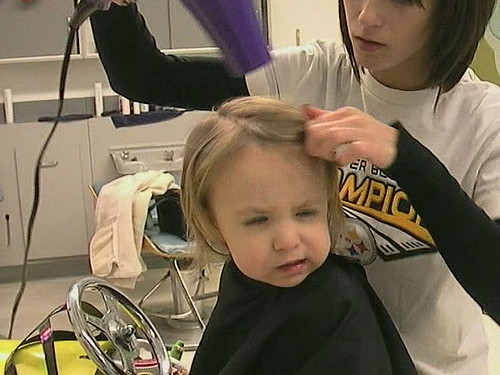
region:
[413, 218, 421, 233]
part of a shirt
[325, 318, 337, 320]
part of a shoulder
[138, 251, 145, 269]
part of a table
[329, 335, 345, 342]
part of a cloth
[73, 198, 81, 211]
part of a drawer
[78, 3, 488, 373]
A child getting their hair styled.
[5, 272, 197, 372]
Racecar chair at a hair salon.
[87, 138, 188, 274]
Sink and chair at a hair salon.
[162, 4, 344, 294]
Drying a child's hair.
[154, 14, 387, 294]
A little girl not enjoying having her hair done.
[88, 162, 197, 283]
A smock on a salon chair.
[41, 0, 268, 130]
A hair dryer.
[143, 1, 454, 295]
Hair dresser with a young client.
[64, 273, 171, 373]
silver steering wheel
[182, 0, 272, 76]
part of a purple hair dryer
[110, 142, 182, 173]
white sink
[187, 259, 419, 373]
black cape to protect neck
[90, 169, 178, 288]
white towel draped over a chair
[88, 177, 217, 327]
black chair with metal legs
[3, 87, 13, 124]
bottle of hair product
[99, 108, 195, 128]
black hand towel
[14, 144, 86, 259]
white cupboard door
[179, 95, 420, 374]
little girl with blonde hair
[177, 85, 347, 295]
small girl getting her hair done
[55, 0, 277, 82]
bright purple hair dryer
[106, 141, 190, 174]
white porcelain sink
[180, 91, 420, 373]
girl wearing black cape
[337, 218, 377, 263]
steelers football team logo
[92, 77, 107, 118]
bottle of hair product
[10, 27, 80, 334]
black electrical cord of blow dryer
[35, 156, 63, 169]
silver handle for cabinet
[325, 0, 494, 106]
girl with short brown hair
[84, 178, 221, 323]
hair stylist beauty chair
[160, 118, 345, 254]
child has blonde hair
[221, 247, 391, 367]
child has black cape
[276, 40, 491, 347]
girl has white shirt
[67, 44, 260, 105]
girl has black shirt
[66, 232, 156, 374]
silver wheel on chair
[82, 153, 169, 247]
white towels on chair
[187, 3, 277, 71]
girl holds purple hair dryer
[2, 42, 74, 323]
black cord on hair dryer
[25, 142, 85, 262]
white drawer behind chair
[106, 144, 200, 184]
white sink behind chair